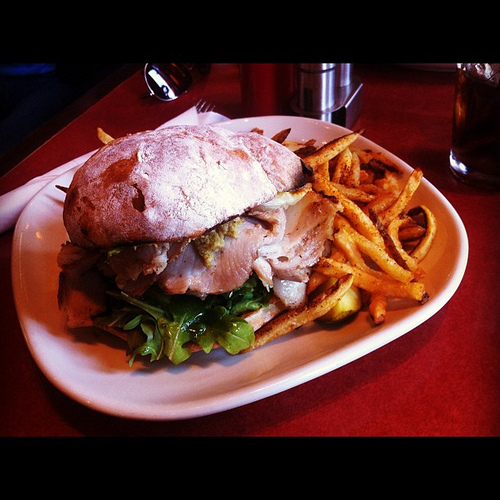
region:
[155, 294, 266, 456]
the plate is white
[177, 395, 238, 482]
the plate is whitethe plate is white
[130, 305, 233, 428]
the plate is white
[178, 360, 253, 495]
the plate is white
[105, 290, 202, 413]
the plate is white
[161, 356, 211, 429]
the plate is white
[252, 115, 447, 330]
french fries next to sandwich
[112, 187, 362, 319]
ham and bacon in sandwich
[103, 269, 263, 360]
lettuce under meat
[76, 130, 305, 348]
hard roll covering meat and lettuce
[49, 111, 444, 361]
sandwich and fries on white plate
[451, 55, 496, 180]
partial view of glass of coke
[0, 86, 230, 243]
silverware wrapped in white napkin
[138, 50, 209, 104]
partial view of sunglasses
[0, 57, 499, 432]
red tablecloth on wooden table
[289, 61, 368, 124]
silver salt and pepper shakers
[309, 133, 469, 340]
Seasoned fries and a pickle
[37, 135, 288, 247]
A piece of bread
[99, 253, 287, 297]
The meat on the sandwich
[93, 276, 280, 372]
Spinach or some form of leafy green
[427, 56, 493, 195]
A dark beverage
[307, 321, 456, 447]
A red table cover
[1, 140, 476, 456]
A square white plate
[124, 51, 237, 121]
A pair of sunglasses on the table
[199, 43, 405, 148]
A silver canister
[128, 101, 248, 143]
The top of a fork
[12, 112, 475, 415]
food on a whhite plate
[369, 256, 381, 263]
black speck of spice on the fry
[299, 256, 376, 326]
fries laying on a pickle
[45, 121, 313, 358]
large sandwich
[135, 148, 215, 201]
white powder on the bun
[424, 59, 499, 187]
glass filled with a dark liquid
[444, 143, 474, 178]
light reflecting on the glass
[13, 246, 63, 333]
shadow on the plate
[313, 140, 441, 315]
golden brown fries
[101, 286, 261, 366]
green leafy lettuce on the bottom of the sandwich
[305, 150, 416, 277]
Seasoned french fries.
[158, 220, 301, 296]
Sandwich filling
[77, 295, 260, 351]
Salad greens with dressing.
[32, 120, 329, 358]
Pork sandwich on a crusty roll.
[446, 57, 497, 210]
Drink glass with dark liquid.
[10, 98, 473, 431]
White plate with meal on it.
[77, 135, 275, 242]
Kaiser roll sandwich.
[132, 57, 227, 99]
Aviator sunglasses partially out of frame.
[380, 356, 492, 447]
Red laminate tabletop.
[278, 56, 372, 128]
Salt and pepper shaker set.